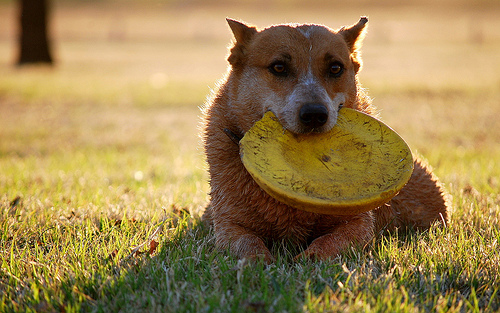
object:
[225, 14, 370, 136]
head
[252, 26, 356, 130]
face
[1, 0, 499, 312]
grass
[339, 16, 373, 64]
ear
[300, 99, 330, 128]
nose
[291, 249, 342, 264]
paws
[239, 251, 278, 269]
paws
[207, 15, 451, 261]
brown dog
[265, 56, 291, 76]
eye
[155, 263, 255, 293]
shadow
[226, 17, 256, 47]
ear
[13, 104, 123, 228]
yellow grass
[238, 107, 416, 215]
frisbee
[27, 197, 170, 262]
grass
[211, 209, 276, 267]
leg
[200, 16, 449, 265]
dog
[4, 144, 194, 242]
green grass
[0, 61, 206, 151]
brown grass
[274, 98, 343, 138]
dog's mouth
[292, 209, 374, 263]
leg